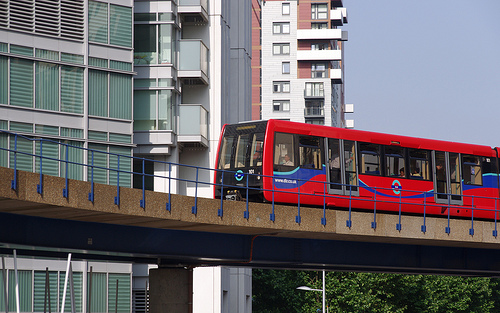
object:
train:
[210, 119, 500, 225]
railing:
[0, 130, 500, 240]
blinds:
[58, 0, 88, 44]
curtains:
[33, 48, 60, 113]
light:
[293, 285, 324, 293]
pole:
[321, 268, 327, 313]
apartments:
[134, 0, 221, 313]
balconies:
[176, 38, 210, 87]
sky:
[339, 0, 500, 150]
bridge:
[0, 128, 500, 278]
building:
[0, 0, 133, 313]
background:
[0, 0, 500, 222]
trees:
[400, 267, 499, 313]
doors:
[324, 136, 360, 198]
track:
[0, 167, 500, 252]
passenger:
[397, 168, 406, 178]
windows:
[273, 131, 295, 167]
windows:
[85, 0, 136, 51]